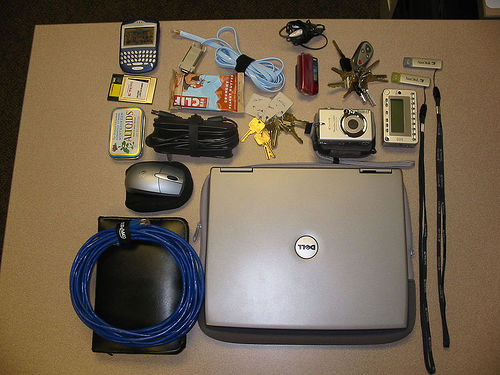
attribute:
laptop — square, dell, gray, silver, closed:
[203, 165, 417, 345]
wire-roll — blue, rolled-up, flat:
[213, 29, 285, 91]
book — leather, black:
[92, 213, 189, 356]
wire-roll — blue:
[70, 216, 206, 346]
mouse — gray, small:
[122, 161, 191, 208]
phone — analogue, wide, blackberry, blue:
[118, 17, 160, 73]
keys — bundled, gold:
[240, 100, 306, 159]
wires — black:
[145, 109, 238, 159]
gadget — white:
[382, 88, 420, 145]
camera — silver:
[316, 108, 376, 146]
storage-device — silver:
[404, 56, 442, 72]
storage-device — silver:
[392, 72, 430, 87]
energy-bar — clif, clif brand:
[169, 71, 247, 114]